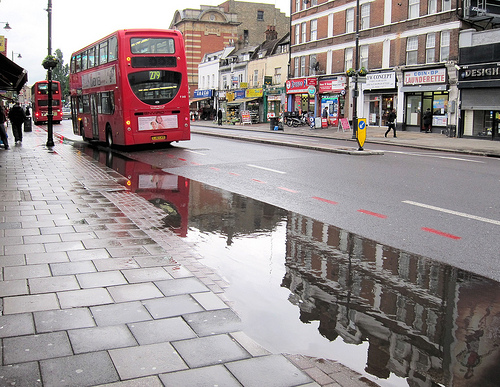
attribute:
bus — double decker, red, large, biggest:
[70, 28, 192, 150]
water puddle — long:
[41, 123, 499, 386]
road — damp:
[28, 103, 499, 386]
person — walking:
[9, 97, 28, 148]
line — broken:
[246, 160, 287, 177]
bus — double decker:
[30, 79, 64, 126]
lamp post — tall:
[44, 1, 59, 152]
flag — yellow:
[354, 116, 370, 152]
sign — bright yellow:
[244, 86, 265, 97]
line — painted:
[312, 191, 340, 208]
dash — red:
[419, 225, 461, 242]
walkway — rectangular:
[189, 124, 384, 156]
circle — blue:
[358, 120, 365, 131]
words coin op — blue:
[410, 66, 439, 77]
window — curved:
[127, 70, 184, 106]